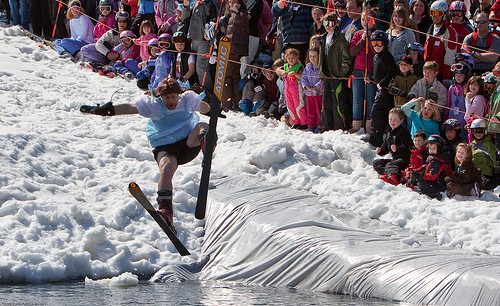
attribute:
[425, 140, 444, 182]
spectator — child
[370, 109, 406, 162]
child — spectator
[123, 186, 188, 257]
ski — black, orange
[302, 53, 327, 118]
spectator — watching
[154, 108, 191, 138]
shirt — white, blue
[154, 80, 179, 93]
wig — red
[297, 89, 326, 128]
pants — pink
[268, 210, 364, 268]
snow — white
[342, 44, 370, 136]
person — watching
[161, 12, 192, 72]
person — watching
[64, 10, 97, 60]
person — watching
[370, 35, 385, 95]
person — watching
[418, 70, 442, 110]
person — watching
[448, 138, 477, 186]
person — watching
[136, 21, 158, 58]
person — watching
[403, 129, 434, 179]
person — watching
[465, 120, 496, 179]
person — watching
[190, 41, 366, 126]
children — watching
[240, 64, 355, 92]
fence — black, orange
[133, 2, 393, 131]
spectators — watching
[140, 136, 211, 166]
shorts — black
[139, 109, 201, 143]
dress — blue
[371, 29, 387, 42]
helmet — black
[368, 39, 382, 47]
goggles — black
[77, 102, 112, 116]
glove — black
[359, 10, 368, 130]
pole — black, orange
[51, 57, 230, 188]
skier — jumping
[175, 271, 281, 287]
sheeting — plastic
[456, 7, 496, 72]
man — watching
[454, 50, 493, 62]
arms — folded